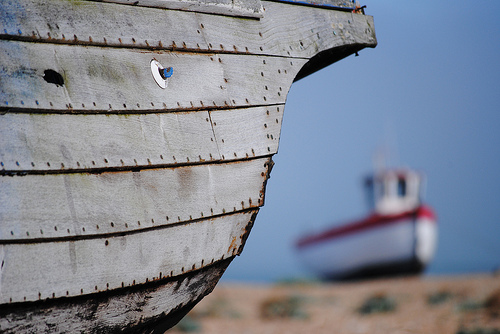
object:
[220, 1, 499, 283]
sky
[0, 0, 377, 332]
boat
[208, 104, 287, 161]
wood panels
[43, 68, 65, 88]
hole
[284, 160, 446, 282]
boat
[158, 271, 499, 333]
shore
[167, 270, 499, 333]
sand